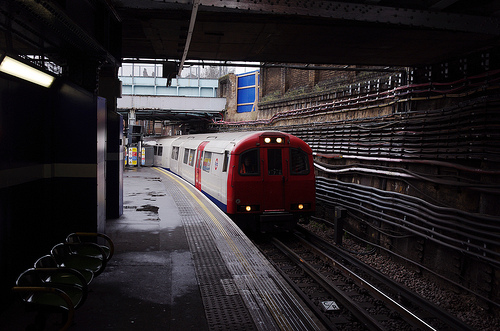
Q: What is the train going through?
A: A tunnel.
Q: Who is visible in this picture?
A: Nobody.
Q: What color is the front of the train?
A: Red.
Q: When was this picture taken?
A: During the day.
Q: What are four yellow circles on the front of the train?
A: Lights.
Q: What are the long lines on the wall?
A: Wires.